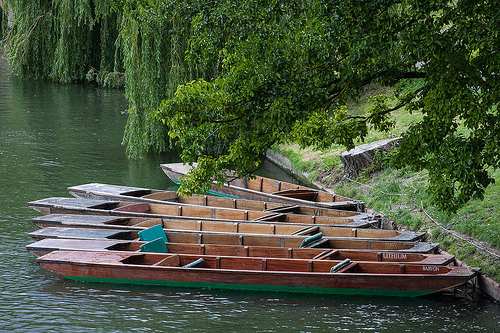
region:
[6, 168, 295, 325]
seven boats in the water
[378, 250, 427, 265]
white letters painted on a boat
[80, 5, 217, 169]
a tree hanging in the water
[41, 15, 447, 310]
a tree hanging over the water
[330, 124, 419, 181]
a tree stump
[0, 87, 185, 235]
a body of water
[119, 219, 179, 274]
blue seats in the boats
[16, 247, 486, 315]
a boat in the water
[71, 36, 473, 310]
tree limbs hanging over the water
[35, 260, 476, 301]
a boat with a green stripe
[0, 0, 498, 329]
overgrown vegetation on the bank of a river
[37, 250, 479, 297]
a wooden canoe for multiple passengers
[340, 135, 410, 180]
a large tree stump on the bank of the river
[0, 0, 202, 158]
weeping willow trees on the bank of a river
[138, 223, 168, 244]
a green cushion in the wooden canoe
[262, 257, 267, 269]
wood slats on the inside of the canoe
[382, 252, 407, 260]
an identifacation number on the inside gunwale of the canoe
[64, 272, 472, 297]
the bottom of the canoe is painted green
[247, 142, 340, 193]
the bank of the river has a small seawall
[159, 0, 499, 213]
a large bushy tree is hanging over the docked canoes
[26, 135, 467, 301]
long and narrow row boats side by side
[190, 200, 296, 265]
wooden supports on side of boat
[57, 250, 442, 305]
green stripe on bottom of boat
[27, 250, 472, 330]
boat floating on green water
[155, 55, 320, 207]
branches hanging over boats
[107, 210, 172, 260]
green cushions upright in boat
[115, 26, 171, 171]
willow branches hanging over water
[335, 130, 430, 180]
thick tree stump on slope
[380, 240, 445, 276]
white writing on inside of boat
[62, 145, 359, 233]
boat angled away from other boats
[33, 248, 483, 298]
long wooden boat docked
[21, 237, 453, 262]
long wooden boat between two boats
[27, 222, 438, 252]
long wooden boat docked between boats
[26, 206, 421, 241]
long wooden boat docked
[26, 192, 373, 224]
long wooden boat between boats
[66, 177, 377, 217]
long wooden boat next to two boats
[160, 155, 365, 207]
long wooden boat at the end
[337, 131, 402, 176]
tree stump in green grass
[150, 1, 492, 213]
bright green tree hanging over boats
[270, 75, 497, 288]
patch of green grass near boats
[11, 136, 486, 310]
Seven boats on a body of water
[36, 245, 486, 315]
Wood boat is green in the base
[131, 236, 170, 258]
Sit of boat is wood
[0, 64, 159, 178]
Body of water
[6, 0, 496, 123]
Canopy of trees close to water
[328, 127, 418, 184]
Trunk cut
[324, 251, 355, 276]
Sits of boat is green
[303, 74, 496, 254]
Green grass on bank of river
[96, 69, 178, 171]
Canopy touching the water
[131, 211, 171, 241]
Green sit of boat